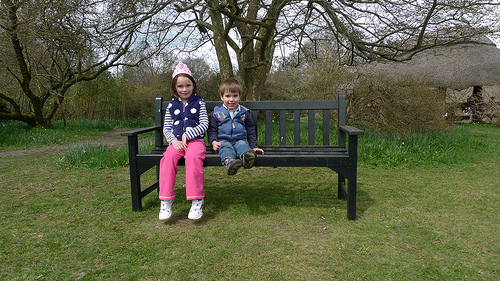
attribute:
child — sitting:
[159, 62, 214, 218]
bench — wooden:
[265, 98, 362, 222]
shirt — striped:
[150, 97, 208, 147]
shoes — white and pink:
[150, 192, 258, 240]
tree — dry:
[3, 2, 489, 97]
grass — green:
[372, 137, 492, 265]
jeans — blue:
[217, 138, 249, 163]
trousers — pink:
[161, 133, 201, 207]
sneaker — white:
[185, 199, 205, 220]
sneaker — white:
[157, 201, 174, 218]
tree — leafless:
[69, 13, 407, 98]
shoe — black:
[240, 147, 257, 169]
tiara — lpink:
[169, 56, 191, 78]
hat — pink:
[168, 60, 195, 80]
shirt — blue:
[210, 102, 262, 151]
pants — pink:
[155, 133, 219, 193]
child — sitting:
[208, 80, 264, 173]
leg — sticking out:
[234, 137, 257, 168]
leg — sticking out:
[219, 139, 242, 175]